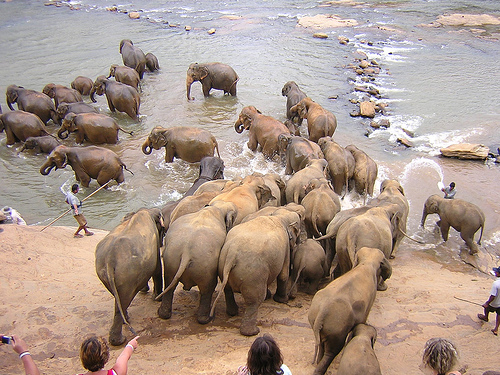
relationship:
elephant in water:
[187, 62, 240, 100] [1, 0, 500, 277]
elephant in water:
[120, 38, 146, 80] [1, 0, 500, 277]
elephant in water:
[90, 75, 140, 120] [1, 0, 500, 277]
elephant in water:
[142, 125, 220, 163] [1, 0, 500, 277]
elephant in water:
[40, 144, 134, 190] [1, 0, 500, 277]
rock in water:
[313, 32, 328, 39] [1, 0, 500, 277]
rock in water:
[361, 100, 376, 117] [1, 0, 500, 277]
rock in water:
[130, 11, 141, 19] [1, 0, 500, 277]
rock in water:
[441, 142, 490, 160] [1, 0, 500, 277]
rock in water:
[208, 28, 217, 34] [1, 0, 500, 277]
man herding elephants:
[65, 185, 95, 238] [2, 39, 485, 374]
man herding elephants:
[478, 266, 500, 335] [2, 39, 485, 374]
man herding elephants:
[442, 182, 456, 200] [2, 39, 485, 374]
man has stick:
[65, 185, 95, 238] [42, 178, 113, 231]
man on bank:
[65, 185, 95, 238] [1, 224, 500, 375]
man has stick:
[478, 266, 500, 335] [453, 296, 482, 308]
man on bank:
[478, 266, 500, 335] [1, 224, 500, 375]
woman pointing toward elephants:
[77, 337, 141, 375] [2, 39, 485, 374]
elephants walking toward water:
[2, 39, 485, 374] [1, 0, 500, 277]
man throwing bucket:
[442, 182, 456, 200] [438, 182, 444, 191]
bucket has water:
[438, 182, 444, 191] [401, 158, 444, 182]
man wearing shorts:
[65, 185, 95, 238] [74, 213, 87, 226]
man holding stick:
[65, 185, 95, 238] [42, 178, 113, 231]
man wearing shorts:
[478, 266, 500, 335] [485, 305, 500, 315]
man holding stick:
[478, 266, 500, 335] [453, 296, 482, 308]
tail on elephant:
[227, 76, 239, 94] [187, 62, 240, 100]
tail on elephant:
[135, 62, 142, 72] [120, 38, 146, 80]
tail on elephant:
[134, 98, 140, 115] [90, 75, 140, 120]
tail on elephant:
[213, 139, 220, 158] [142, 125, 220, 163]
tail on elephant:
[120, 164, 134, 175] [40, 144, 134, 190]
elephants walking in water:
[0, 39, 485, 254] [1, 0, 500, 277]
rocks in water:
[338, 35, 390, 138] [1, 0, 500, 277]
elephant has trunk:
[142, 125, 220, 163] [142, 138, 152, 155]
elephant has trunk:
[40, 144, 134, 190] [40, 160, 55, 176]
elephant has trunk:
[58, 112, 133, 145] [58, 126, 69, 139]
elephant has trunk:
[235, 106, 291, 160] [235, 119, 245, 134]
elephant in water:
[145, 53, 160, 72] [1, 0, 500, 277]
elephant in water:
[18, 135, 60, 155] [1, 0, 500, 277]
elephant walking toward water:
[95, 208, 165, 344] [1, 0, 500, 277]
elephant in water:
[58, 112, 133, 145] [1, 0, 500, 277]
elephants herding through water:
[2, 39, 485, 374] [1, 0, 500, 277]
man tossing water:
[442, 182, 456, 200] [401, 158, 444, 182]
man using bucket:
[442, 182, 456, 200] [438, 182, 444, 191]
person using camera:
[0, 333, 40, 375] [2, 335, 12, 343]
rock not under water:
[361, 100, 376, 117] [1, 0, 500, 277]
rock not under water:
[313, 32, 328, 39] [1, 0, 500, 277]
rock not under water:
[208, 28, 217, 34] [1, 0, 500, 277]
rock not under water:
[130, 11, 141, 19] [1, 0, 500, 277]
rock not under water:
[441, 142, 490, 160] [1, 0, 500, 277]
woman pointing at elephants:
[77, 337, 141, 375] [2, 39, 485, 374]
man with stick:
[65, 185, 95, 238] [42, 178, 113, 231]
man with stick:
[478, 266, 500, 335] [453, 296, 482, 308]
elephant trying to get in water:
[217, 210, 303, 336] [1, 0, 500, 277]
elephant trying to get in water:
[155, 201, 238, 324] [1, 0, 500, 277]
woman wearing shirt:
[77, 337, 141, 375] [76, 369, 116, 374]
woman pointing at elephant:
[77, 337, 141, 375] [155, 201, 238, 324]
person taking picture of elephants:
[0, 333, 40, 375] [2, 39, 485, 374]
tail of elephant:
[227, 76, 239, 94] [187, 62, 240, 100]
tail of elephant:
[135, 62, 142, 72] [120, 38, 146, 80]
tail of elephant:
[134, 98, 140, 115] [90, 75, 140, 120]